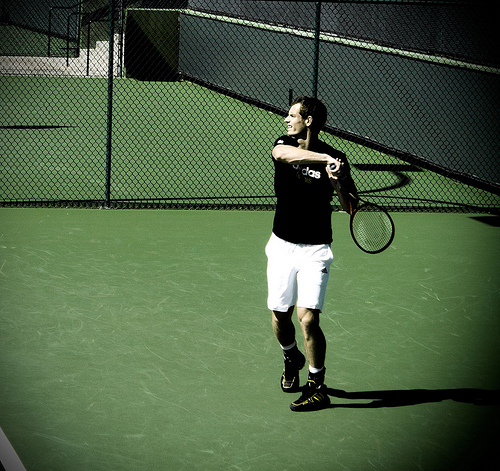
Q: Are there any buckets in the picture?
A: No, there are no buckets.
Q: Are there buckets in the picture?
A: No, there are no buckets.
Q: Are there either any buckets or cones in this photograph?
A: No, there are no buckets or cones.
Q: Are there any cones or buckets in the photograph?
A: No, there are no buckets or cones.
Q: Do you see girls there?
A: No, there are no girls.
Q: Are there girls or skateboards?
A: No, there are no girls or skateboards.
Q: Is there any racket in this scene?
A: Yes, there is a racket.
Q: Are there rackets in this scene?
A: Yes, there is a racket.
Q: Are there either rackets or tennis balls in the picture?
A: Yes, there is a racket.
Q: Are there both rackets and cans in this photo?
A: No, there is a racket but no cans.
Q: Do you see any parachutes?
A: No, there are no parachutes.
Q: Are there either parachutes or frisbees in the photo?
A: No, there are no parachutes or frisbees.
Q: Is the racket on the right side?
A: Yes, the racket is on the right of the image.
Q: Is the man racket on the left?
A: No, the racket is on the right of the image.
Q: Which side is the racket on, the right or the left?
A: The racket is on the right of the image.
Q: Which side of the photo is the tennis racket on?
A: The tennis racket is on the right of the image.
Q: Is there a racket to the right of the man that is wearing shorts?
A: Yes, there is a racket to the right of the man.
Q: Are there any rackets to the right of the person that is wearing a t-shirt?
A: Yes, there is a racket to the right of the man.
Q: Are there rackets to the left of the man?
A: No, the racket is to the right of the man.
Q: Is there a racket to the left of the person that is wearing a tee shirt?
A: No, the racket is to the right of the man.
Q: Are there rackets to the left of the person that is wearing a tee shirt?
A: No, the racket is to the right of the man.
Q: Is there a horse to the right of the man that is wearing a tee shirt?
A: No, there is a racket to the right of the man.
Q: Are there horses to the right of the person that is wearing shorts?
A: No, there is a racket to the right of the man.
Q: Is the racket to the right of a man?
A: Yes, the racket is to the right of a man.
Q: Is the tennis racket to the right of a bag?
A: No, the tennis racket is to the right of a man.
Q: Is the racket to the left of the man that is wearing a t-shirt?
A: No, the racket is to the right of the man.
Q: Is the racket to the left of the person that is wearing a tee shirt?
A: No, the racket is to the right of the man.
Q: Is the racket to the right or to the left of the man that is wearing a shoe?
A: The racket is to the right of the man.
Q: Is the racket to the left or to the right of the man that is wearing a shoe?
A: The racket is to the right of the man.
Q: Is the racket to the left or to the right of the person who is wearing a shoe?
A: The racket is to the right of the man.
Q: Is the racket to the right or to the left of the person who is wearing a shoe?
A: The racket is to the right of the man.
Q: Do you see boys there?
A: No, there are no boys.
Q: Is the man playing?
A: Yes, the man is playing.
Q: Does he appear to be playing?
A: Yes, the man is playing.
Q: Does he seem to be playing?
A: Yes, the man is playing.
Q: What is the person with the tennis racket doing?
A: The man is playing.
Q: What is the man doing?
A: The man is playing.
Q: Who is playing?
A: The man is playing.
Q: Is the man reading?
A: No, the man is playing.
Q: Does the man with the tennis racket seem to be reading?
A: No, the man is playing.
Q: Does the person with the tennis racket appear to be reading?
A: No, the man is playing.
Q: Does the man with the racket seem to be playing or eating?
A: The man is playing.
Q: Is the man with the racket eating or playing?
A: The man is playing.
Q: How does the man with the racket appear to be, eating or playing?
A: The man is playing.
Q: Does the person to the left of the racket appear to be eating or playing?
A: The man is playing.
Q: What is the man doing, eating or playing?
A: The man is playing.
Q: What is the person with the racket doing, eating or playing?
A: The man is playing.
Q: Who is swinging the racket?
A: The man is swinging the racket.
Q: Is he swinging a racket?
A: Yes, the man is swinging a racket.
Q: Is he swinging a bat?
A: No, the man is swinging a racket.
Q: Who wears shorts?
A: The man wears shorts.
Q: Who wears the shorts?
A: The man wears shorts.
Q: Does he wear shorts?
A: Yes, the man wears shorts.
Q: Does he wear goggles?
A: No, the man wears shorts.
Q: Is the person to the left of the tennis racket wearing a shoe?
A: Yes, the man is wearing a shoe.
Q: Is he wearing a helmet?
A: No, the man is wearing a shoe.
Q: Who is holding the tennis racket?
A: The man is holding the tennis racket.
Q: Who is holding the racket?
A: The man is holding the tennis racket.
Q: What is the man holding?
A: The man is holding the tennis racket.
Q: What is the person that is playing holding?
A: The man is holding the tennis racket.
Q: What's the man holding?
A: The man is holding the tennis racket.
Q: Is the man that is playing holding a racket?
A: Yes, the man is holding a racket.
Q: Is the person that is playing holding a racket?
A: Yes, the man is holding a racket.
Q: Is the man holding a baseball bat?
A: No, the man is holding a racket.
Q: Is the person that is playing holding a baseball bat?
A: No, the man is holding a racket.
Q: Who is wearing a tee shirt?
A: The man is wearing a tee shirt.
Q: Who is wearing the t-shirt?
A: The man is wearing a tee shirt.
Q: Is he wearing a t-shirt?
A: Yes, the man is wearing a t-shirt.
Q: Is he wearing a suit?
A: No, the man is wearing a t-shirt.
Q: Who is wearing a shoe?
A: The man is wearing a shoe.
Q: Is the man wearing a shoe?
A: Yes, the man is wearing a shoe.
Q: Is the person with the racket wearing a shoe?
A: Yes, the man is wearing a shoe.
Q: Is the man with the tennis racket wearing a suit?
A: No, the man is wearing a shoe.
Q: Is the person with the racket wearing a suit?
A: No, the man is wearing a shoe.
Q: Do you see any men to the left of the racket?
A: Yes, there is a man to the left of the racket.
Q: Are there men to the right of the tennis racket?
A: No, the man is to the left of the tennis racket.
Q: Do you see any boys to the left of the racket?
A: No, there is a man to the left of the racket.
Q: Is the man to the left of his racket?
A: Yes, the man is to the left of the racket.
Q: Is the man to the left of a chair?
A: No, the man is to the left of the racket.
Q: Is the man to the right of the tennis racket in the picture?
A: No, the man is to the left of the tennis racket.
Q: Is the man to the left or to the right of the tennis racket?
A: The man is to the left of the tennis racket.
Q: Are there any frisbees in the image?
A: No, there are no frisbees.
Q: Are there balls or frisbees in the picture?
A: No, there are no frisbees or balls.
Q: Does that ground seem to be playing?
A: Yes, the ground is playing.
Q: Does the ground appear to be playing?
A: Yes, the ground is playing.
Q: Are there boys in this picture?
A: No, there are no boys.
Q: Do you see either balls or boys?
A: No, there are no boys or balls.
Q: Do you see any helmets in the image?
A: No, there are no helmets.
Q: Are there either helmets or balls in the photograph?
A: No, there are no helmets or balls.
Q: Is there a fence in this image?
A: Yes, there is a fence.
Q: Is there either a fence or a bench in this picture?
A: Yes, there is a fence.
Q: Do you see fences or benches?
A: Yes, there is a fence.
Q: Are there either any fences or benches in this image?
A: Yes, there is a fence.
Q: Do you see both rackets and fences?
A: Yes, there are both a fence and a racket.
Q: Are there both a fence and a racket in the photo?
A: Yes, there are both a fence and a racket.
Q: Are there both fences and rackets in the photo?
A: Yes, there are both a fence and a racket.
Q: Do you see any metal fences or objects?
A: Yes, there is a metal fence.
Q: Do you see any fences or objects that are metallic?
A: Yes, the fence is metallic.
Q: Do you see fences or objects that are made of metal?
A: Yes, the fence is made of metal.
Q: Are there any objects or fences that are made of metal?
A: Yes, the fence is made of metal.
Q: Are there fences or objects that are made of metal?
A: Yes, the fence is made of metal.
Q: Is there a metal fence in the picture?
A: Yes, there is a metal fence.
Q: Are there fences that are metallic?
A: Yes, there is a fence that is metallic.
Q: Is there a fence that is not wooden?
A: Yes, there is a metallic fence.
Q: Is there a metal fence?
A: Yes, there is a fence that is made of metal.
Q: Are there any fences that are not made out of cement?
A: Yes, there is a fence that is made of metal.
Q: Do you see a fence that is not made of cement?
A: Yes, there is a fence that is made of metal.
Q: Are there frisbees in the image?
A: No, there are no frisbees.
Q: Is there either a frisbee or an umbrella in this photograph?
A: No, there are no frisbees or umbrellas.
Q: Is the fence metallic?
A: Yes, the fence is metallic.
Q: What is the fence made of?
A: The fence is made of metal.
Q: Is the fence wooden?
A: No, the fence is metallic.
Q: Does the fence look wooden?
A: No, the fence is metallic.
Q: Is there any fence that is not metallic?
A: No, there is a fence but it is metallic.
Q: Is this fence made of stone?
A: No, the fence is made of metal.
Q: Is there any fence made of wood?
A: No, there is a fence but it is made of metal.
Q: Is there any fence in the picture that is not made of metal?
A: No, there is a fence but it is made of metal.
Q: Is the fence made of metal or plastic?
A: The fence is made of metal.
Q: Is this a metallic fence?
A: Yes, this is a metallic fence.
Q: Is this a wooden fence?
A: No, this is a metallic fence.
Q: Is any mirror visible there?
A: No, there are no mirrors.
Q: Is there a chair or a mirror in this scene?
A: No, there are no mirrors or chairs.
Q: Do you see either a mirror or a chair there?
A: No, there are no mirrors or chairs.